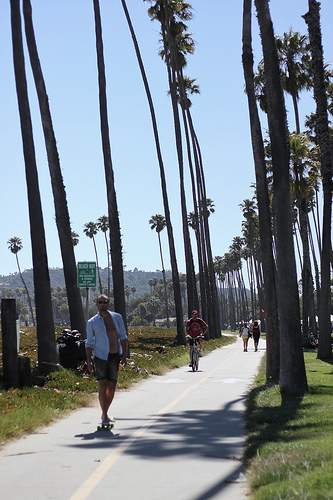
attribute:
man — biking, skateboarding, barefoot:
[87, 294, 126, 421]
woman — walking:
[240, 322, 250, 352]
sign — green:
[77, 261, 95, 287]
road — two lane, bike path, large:
[11, 346, 265, 497]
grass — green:
[244, 348, 331, 499]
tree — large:
[11, 29, 58, 378]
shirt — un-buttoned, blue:
[86, 311, 128, 361]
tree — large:
[253, 0, 309, 397]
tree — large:
[241, 0, 279, 384]